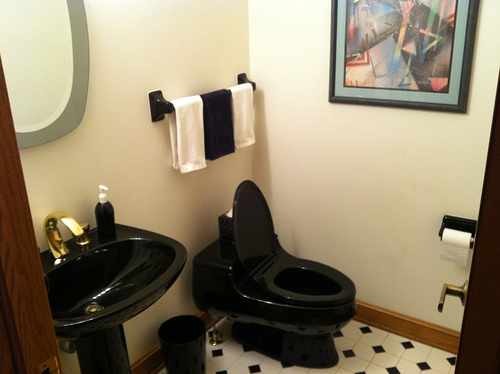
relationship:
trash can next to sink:
[158, 314, 208, 372] [40, 214, 186, 373]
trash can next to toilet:
[158, 314, 208, 372] [193, 180, 356, 368]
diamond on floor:
[375, 345, 385, 354] [159, 315, 457, 371]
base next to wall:
[131, 300, 462, 371] [19, 0, 498, 371]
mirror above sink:
[0, 0, 90, 148] [40, 214, 186, 373]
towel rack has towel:
[150, 73, 265, 123] [202, 89, 237, 159]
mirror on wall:
[0, 0, 90, 148] [19, 0, 498, 371]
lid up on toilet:
[233, 180, 280, 273] [193, 180, 356, 368]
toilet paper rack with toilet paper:
[439, 216, 477, 247] [442, 229, 471, 261]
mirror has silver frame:
[0, 0, 90, 148] [16, 0, 89, 147]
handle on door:
[438, 284, 468, 314] [454, 73, 499, 371]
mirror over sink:
[0, 0, 90, 148] [40, 214, 186, 373]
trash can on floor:
[158, 314, 208, 372] [159, 315, 457, 371]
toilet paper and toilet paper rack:
[442, 229, 471, 261] [439, 216, 477, 247]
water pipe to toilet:
[204, 311, 224, 345] [193, 180, 356, 368]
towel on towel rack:
[202, 89, 237, 159] [150, 73, 265, 123]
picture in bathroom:
[329, 0, 481, 112] [0, 3, 499, 372]